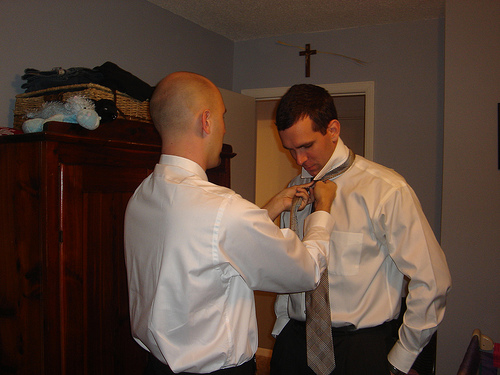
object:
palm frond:
[277, 37, 367, 66]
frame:
[240, 80, 375, 160]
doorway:
[255, 94, 366, 206]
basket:
[13, 83, 153, 123]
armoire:
[0, 121, 234, 375]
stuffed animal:
[22, 94, 102, 134]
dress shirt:
[120, 152, 331, 373]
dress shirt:
[270, 137, 452, 374]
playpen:
[457, 328, 497, 374]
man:
[271, 82, 454, 374]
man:
[123, 73, 338, 372]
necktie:
[289, 147, 354, 375]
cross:
[299, 43, 317, 77]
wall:
[233, 12, 494, 371]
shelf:
[0, 121, 238, 375]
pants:
[268, 319, 405, 375]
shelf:
[3, 80, 159, 131]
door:
[210, 83, 364, 208]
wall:
[3, 2, 230, 124]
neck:
[306, 145, 347, 180]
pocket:
[327, 229, 365, 277]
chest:
[284, 182, 379, 247]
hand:
[379, 360, 407, 375]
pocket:
[371, 352, 392, 375]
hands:
[277, 182, 315, 211]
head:
[147, 72, 227, 169]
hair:
[274, 83, 340, 136]